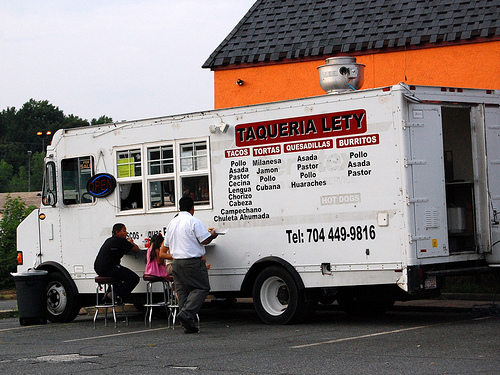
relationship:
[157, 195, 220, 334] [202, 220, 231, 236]
man eating food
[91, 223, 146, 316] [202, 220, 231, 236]
people eating food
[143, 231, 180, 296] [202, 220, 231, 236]
girl eating food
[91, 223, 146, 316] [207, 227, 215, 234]
people eating food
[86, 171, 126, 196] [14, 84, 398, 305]
hat hanging from truck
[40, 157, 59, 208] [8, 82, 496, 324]
side mirrors on food truck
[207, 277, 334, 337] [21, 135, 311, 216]
tire on food truck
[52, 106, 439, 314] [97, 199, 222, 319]
food truck serving customers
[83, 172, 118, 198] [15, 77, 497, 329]
sign on truck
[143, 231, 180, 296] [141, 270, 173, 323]
girl sitting on stool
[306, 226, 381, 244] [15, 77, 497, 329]
number on truck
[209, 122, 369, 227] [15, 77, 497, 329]
menu on truck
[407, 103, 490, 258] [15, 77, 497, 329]
door on truck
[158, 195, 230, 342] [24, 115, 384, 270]
man walking toward truck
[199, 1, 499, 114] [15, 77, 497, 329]
building behind truck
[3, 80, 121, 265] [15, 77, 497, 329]
trees behind truck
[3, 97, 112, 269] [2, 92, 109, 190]
leaves on trees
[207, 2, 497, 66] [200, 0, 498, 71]
shingles on roof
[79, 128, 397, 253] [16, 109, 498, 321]
side on truck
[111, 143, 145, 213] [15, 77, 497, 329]
window on truck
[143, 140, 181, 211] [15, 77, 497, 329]
window on truck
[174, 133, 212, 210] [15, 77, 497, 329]
window on truck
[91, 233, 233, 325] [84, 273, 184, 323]
people sitting on stools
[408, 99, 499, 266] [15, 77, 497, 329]
open door on back of truck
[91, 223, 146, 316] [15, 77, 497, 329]
people on side of truck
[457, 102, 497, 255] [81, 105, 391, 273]
door on truck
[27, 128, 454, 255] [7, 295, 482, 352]
truck in parking lot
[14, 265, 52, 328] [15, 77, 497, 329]
garbage can by truck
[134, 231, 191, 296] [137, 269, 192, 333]
girl sitting on stool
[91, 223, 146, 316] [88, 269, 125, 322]
people sitting on stool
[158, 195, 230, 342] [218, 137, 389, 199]
man with food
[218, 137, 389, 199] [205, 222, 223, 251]
food in hands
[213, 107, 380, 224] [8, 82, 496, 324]
writing on food truck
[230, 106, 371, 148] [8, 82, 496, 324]
sign on food truck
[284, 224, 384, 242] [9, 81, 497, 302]
number on truck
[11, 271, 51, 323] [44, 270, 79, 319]
trash can by tire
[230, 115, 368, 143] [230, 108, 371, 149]
words on sign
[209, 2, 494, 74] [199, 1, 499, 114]
roof on building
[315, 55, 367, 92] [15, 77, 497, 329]
exhaust fan on truck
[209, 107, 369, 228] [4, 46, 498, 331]
menu on side of truck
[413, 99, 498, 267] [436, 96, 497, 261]
open door on food truck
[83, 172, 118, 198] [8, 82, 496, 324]
sign on food truck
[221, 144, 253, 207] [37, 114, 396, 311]
menu items on side of truck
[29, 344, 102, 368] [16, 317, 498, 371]
hole in asphalt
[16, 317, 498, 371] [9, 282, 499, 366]
asphalt in parking lot